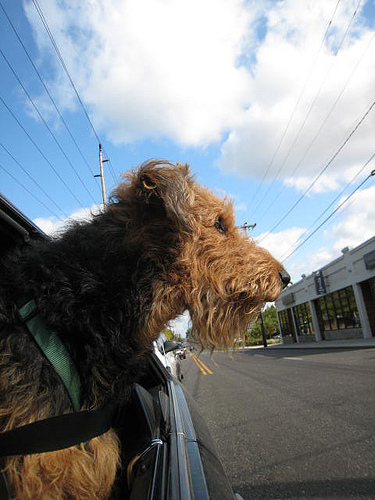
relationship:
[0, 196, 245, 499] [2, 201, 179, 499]
car has window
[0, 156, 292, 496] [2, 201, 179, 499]
dog looking out window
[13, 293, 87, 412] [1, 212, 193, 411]
collar on neck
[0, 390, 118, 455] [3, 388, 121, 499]
safety belt across chest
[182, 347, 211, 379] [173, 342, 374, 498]
lines on road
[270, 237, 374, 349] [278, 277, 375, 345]
store front has windows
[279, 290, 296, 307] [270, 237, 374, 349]
sign on store front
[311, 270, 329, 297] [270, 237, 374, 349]
sign on store front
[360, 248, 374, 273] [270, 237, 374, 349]
sign on store front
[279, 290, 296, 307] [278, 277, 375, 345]
sign over windows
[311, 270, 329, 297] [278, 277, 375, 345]
sign over windows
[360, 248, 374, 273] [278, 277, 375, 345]
sign over windows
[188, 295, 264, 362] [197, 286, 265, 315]
wiry fur on chin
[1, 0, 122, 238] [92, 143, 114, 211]
power lines on pole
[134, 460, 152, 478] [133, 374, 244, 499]
lock button on door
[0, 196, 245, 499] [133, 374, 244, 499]
car has door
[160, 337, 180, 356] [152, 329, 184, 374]
side view mirror on car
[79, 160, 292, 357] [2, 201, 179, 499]
head outside window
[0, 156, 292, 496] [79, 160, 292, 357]
dog has head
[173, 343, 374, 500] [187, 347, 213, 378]
street has lines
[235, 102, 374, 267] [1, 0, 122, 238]
telephone lines and power lines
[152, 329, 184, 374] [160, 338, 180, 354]
car has rear view mirror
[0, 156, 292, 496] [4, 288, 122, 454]
dog has restraints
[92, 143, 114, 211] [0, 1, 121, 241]
pole has wires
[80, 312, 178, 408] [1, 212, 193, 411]
fur on neck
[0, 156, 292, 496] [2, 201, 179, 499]
dog looking from window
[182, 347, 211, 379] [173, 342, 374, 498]
lines in road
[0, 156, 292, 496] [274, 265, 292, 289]
dog has nose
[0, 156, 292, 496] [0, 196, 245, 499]
dog in car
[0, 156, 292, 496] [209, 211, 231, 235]
dog has right eye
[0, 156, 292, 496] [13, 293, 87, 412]
dog wearing collar